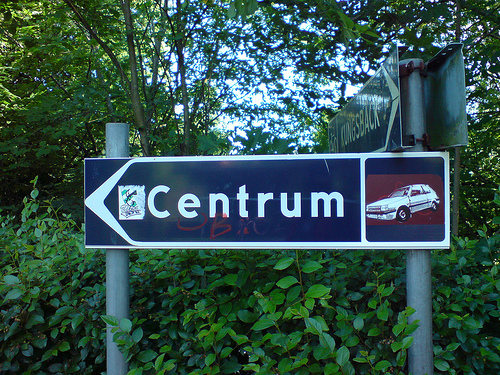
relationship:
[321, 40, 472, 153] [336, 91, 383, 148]
sign says kingback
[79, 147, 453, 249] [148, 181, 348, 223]
road sign points to centram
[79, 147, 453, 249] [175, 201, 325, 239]
road sign has graffiti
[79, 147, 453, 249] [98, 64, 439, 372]
road sign on posts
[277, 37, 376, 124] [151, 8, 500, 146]
sun in sky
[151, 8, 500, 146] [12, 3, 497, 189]
sky shining through leaves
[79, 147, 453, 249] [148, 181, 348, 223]
road sign says centram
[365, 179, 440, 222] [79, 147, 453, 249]
car on road sign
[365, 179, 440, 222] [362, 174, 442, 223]
car has red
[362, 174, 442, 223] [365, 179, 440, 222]
red around car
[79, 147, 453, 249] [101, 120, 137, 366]
road sign on post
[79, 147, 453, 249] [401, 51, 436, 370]
road sign on post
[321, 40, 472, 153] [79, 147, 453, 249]
sign perpendicular to road sign